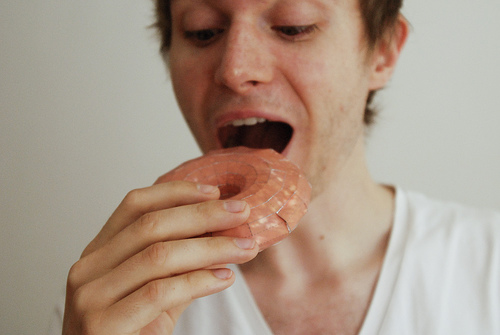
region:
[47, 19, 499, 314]
a man is eating a donut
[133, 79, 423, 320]
guy wearing white shirt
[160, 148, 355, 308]
guy wearing white shirt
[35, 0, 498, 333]
man eating a doughnut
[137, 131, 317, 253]
doughnut in a hand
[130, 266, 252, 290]
pinky of a man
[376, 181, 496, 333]
white v-neck t-shirt on a man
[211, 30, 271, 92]
nose of a man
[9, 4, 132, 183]
white wall behind man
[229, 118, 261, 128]
front teeth of a man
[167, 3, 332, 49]
eyes of a man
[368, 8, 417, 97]
left ear of a man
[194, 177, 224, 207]
index finger nail on a man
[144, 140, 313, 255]
The donut is glazed.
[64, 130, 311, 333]
Man holding a donut.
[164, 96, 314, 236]
The man is eating a donut.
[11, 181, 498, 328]
The man's shirt is white.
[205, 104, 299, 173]
The man's mouth is open.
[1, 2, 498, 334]
The wall is white.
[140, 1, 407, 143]
The man has short hair.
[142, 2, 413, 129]
The man's hair is brown.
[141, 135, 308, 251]
No bites out of donut.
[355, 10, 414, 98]
One ear is visible.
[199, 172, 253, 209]
hole of pale glazed donut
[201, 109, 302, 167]
man's mouth about to take a bite of food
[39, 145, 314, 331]
Caucasian male hand holding a dount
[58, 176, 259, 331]
four male fingers facing the same direction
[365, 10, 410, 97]
left Caucasian male ear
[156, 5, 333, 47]
male eyes looking down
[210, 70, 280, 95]
nostrils of white male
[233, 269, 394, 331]
closeup of white V neck T shirt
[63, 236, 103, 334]
knuckles of Caucasian male hand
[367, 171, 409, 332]
front edge of white V neck T shirt